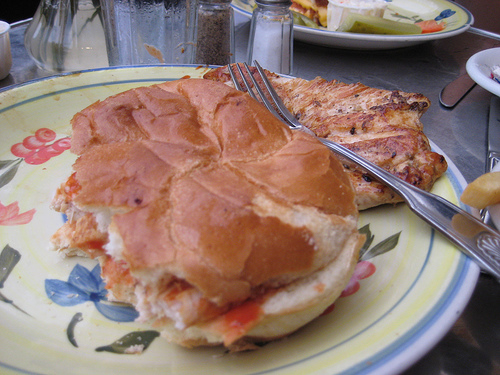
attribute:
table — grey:
[2, 23, 497, 224]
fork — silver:
[228, 62, 326, 145]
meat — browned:
[204, 64, 446, 206]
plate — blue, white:
[19, 74, 153, 181]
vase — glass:
[29, 1, 121, 90]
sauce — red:
[204, 296, 281, 345]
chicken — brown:
[201, 60, 448, 211]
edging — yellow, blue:
[357, 108, 484, 373]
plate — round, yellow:
[8, 65, 483, 373]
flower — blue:
[45, 250, 129, 317]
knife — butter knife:
[432, 69, 475, 119]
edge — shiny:
[298, 35, 498, 175]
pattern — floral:
[0, 121, 408, 361]